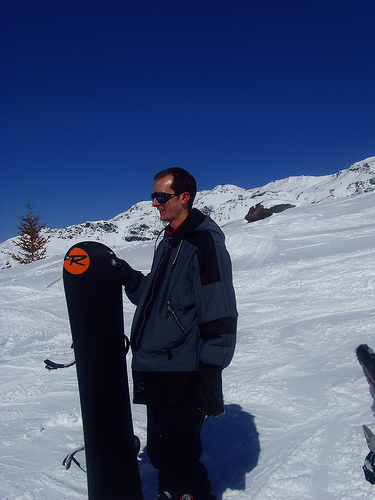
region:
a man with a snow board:
[56, 167, 238, 494]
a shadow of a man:
[213, 391, 262, 486]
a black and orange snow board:
[63, 238, 129, 498]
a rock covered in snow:
[244, 192, 289, 221]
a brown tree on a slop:
[14, 201, 48, 265]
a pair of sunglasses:
[149, 187, 174, 205]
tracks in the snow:
[266, 232, 354, 304]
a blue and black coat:
[132, 216, 235, 404]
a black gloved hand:
[200, 383, 225, 418]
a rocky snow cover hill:
[313, 165, 367, 200]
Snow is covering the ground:
[0, 198, 371, 496]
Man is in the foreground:
[92, 158, 242, 492]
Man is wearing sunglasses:
[139, 183, 188, 206]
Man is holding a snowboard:
[49, 235, 154, 496]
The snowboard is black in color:
[55, 233, 151, 495]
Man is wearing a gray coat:
[113, 205, 249, 387]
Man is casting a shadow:
[152, 382, 275, 497]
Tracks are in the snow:
[3, 258, 371, 496]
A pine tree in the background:
[12, 187, 51, 264]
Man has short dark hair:
[144, 159, 204, 211]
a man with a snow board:
[59, 159, 252, 492]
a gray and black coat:
[120, 211, 238, 407]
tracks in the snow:
[279, 257, 336, 363]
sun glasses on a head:
[150, 192, 178, 208]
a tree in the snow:
[13, 190, 47, 268]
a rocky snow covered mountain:
[305, 163, 374, 198]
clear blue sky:
[6, 23, 361, 154]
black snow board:
[59, 235, 143, 479]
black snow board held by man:
[55, 254, 145, 490]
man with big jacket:
[122, 173, 242, 472]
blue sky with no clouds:
[18, 21, 69, 76]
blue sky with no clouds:
[29, 88, 109, 139]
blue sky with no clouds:
[33, 137, 79, 187]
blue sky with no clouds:
[67, 30, 113, 75]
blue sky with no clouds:
[148, 16, 184, 58]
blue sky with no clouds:
[171, 64, 205, 100]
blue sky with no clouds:
[208, 64, 273, 121]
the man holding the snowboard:
[49, 124, 234, 497]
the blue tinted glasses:
[144, 188, 176, 205]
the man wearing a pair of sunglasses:
[147, 178, 194, 220]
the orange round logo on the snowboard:
[64, 243, 97, 280]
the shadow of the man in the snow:
[222, 386, 267, 499]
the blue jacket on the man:
[124, 223, 242, 384]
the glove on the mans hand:
[190, 376, 228, 422]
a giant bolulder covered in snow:
[242, 195, 297, 228]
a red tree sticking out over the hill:
[8, 199, 50, 266]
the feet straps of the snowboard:
[23, 321, 80, 482]